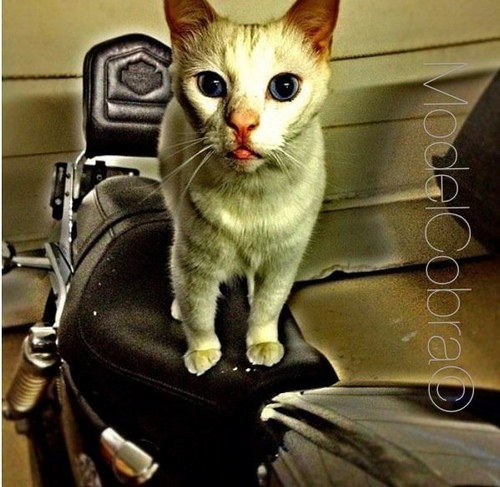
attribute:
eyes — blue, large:
[193, 64, 309, 110]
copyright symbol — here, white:
[416, 359, 481, 415]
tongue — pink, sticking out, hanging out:
[228, 139, 256, 165]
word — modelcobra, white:
[411, 54, 480, 368]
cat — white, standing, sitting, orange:
[140, 2, 350, 378]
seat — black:
[61, 167, 350, 483]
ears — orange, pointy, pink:
[156, 1, 357, 61]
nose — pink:
[221, 97, 271, 134]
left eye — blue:
[259, 68, 311, 108]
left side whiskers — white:
[265, 140, 362, 209]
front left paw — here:
[235, 324, 290, 370]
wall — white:
[6, 5, 500, 303]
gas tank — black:
[43, 152, 154, 216]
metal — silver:
[42, 145, 94, 290]